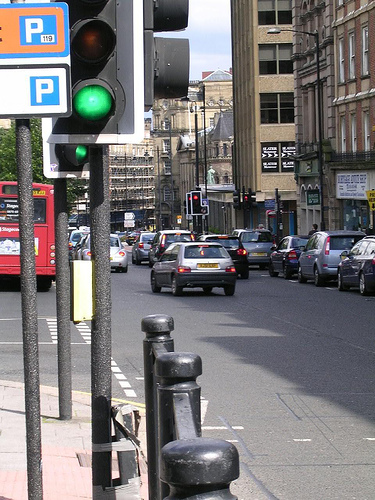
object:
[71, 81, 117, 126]
traffic light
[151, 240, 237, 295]
car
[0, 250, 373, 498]
street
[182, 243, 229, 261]
windshield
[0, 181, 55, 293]
bus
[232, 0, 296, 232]
building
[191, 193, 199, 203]
stop light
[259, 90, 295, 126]
window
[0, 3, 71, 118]
street sign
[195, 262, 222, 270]
tag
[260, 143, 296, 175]
sign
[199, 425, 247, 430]
marking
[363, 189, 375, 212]
road sign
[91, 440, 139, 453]
duct tape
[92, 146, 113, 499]
pole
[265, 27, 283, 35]
street lamp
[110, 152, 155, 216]
scaffolding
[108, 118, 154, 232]
building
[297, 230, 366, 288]
car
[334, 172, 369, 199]
sign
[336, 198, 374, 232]
store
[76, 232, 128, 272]
car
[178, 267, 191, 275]
light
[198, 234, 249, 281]
car